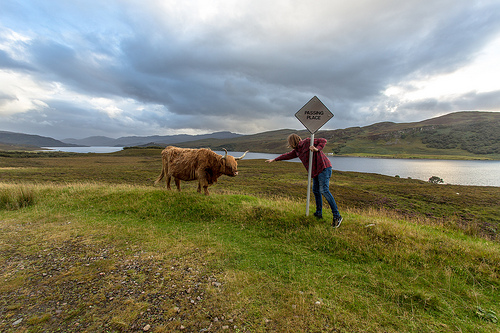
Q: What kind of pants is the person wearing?
A: Jeans.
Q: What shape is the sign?
A: Rectangle.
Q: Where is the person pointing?
A: To the left.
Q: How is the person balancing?
A: She is holding the sign post.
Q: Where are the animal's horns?
A: On top of its head.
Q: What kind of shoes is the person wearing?
A: Sneakers.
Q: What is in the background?
A: Mountains.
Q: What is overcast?
A: The sky.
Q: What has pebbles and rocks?
A: The ground.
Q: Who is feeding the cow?
A: A woman.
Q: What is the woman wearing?
A: Red plaid shirt.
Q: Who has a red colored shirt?
A: The man.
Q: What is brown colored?
A: Buffalo.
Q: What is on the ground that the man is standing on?
A: Grass.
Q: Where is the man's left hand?
A: Holding onto sign.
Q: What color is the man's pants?
A: Blue.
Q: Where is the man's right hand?
A: Reaching toward animal.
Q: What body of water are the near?
A: River.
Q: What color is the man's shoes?
A: Black.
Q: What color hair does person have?
A: Blonde.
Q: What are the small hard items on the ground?
A: Rocks.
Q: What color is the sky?
A: Blue.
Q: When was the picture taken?
A: Daytime.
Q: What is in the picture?
A: A man and a steer.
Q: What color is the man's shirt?
A: Red.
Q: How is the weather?
A: Cloudy.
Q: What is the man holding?
A: A sign.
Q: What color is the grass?
A: Green.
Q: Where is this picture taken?
A: In a field.